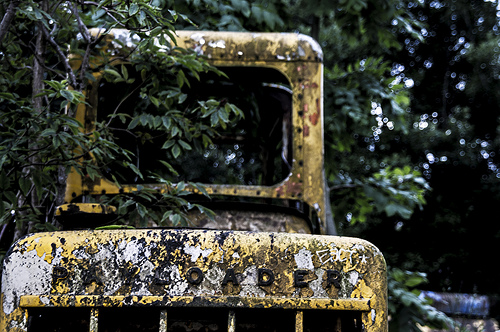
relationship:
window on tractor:
[91, 59, 295, 189] [0, 24, 498, 330]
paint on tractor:
[0, 227, 379, 305] [0, 24, 498, 330]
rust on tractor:
[274, 62, 323, 198] [0, 24, 498, 330]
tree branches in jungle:
[1, 12, 230, 233] [0, 3, 495, 328]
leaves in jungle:
[357, 79, 419, 223] [0, 3, 495, 328]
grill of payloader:
[16, 293, 373, 330] [0, 26, 498, 330]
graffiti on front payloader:
[317, 243, 370, 267] [0, 26, 498, 330]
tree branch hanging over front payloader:
[30, 14, 94, 125] [0, 26, 498, 330]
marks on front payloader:
[155, 228, 185, 250] [0, 26, 498, 330]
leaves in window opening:
[121, 36, 249, 172] [93, 65, 296, 185]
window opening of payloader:
[93, 65, 296, 185] [0, 26, 498, 330]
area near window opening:
[275, 170, 309, 197] [97, 65, 297, 187]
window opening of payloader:
[97, 65, 297, 187] [0, 26, 498, 330]